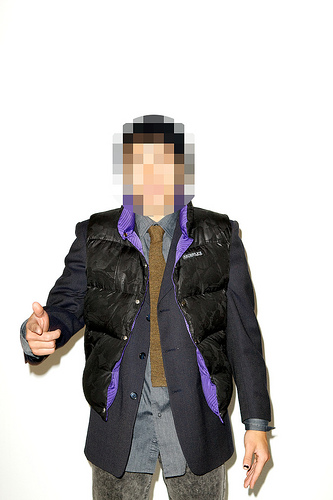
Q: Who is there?
A: Man.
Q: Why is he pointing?
A: Picture.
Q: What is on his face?
A: Blur.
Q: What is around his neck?
A: Tie.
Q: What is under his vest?
A: Suit jacket.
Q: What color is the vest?
A: Black.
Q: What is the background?
A: White.